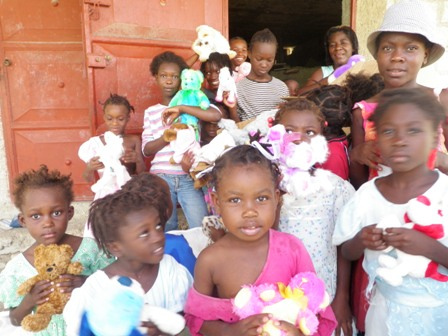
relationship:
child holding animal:
[180, 144, 338, 335] [232, 268, 326, 335]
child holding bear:
[141, 50, 223, 232] [168, 66, 209, 128]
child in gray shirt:
[235, 29, 289, 121] [235, 74, 288, 122]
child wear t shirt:
[177, 143, 339, 334] [184, 228, 339, 336]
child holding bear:
[4, 162, 100, 334] [12, 240, 85, 331]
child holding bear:
[142, 52, 224, 227] [194, 243, 349, 328]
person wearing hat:
[356, 1, 446, 120] [362, 1, 443, 56]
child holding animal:
[180, 144, 338, 335] [231, 271, 333, 334]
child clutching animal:
[180, 144, 338, 335] [231, 271, 333, 334]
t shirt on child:
[184, 226, 339, 334] [180, 144, 338, 335]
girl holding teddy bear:
[266, 91, 353, 298] [282, 137, 349, 309]